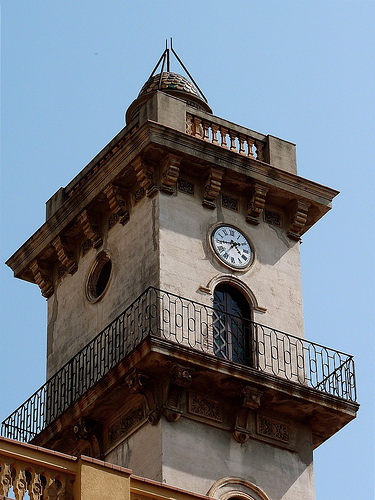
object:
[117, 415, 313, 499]
cement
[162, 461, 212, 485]
edge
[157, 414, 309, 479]
shade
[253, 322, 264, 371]
bar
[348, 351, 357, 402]
bar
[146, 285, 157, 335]
bar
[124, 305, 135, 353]
bar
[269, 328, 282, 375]
bar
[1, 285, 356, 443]
metal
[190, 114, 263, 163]
railing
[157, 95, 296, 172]
roof balcony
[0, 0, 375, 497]
photo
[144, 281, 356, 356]
cat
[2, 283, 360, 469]
balcony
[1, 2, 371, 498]
sky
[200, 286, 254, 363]
window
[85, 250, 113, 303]
window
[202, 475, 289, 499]
round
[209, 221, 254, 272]
clock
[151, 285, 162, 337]
bar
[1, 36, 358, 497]
tower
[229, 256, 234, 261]
roman numerals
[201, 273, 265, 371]
door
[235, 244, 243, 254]
hands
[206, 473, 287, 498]
doorway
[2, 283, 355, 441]
fence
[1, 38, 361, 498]
building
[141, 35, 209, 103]
pipes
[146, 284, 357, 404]
wrought iron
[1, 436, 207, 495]
part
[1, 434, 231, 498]
fence